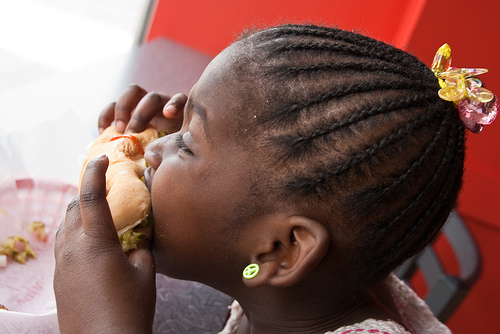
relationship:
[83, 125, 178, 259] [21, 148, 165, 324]
food in a girl's hand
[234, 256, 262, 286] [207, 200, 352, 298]
earring in a ear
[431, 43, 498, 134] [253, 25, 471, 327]
barrette in a hair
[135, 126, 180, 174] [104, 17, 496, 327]
nose of a girl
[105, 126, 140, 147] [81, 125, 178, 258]
ketchup on a food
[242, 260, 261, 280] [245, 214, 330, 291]
earring in ear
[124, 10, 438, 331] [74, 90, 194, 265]
girl eating food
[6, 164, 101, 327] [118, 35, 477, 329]
food basket in front of a girl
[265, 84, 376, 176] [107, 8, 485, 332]
braid on girl's head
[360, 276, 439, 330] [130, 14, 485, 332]
clothes on girl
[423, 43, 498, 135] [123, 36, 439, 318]
barrette in girl's hair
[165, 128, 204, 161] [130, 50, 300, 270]
eyelash on girl's face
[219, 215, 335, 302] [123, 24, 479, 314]
ear on girl's head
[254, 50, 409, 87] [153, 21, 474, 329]
braid on girl's head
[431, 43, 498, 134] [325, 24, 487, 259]
barrette in hair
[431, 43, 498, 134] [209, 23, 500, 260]
barrette in her girl's hair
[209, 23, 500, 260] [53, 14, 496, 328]
girl's hair of girl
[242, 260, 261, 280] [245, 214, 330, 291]
earring in her ear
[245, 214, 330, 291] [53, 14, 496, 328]
ear of girl